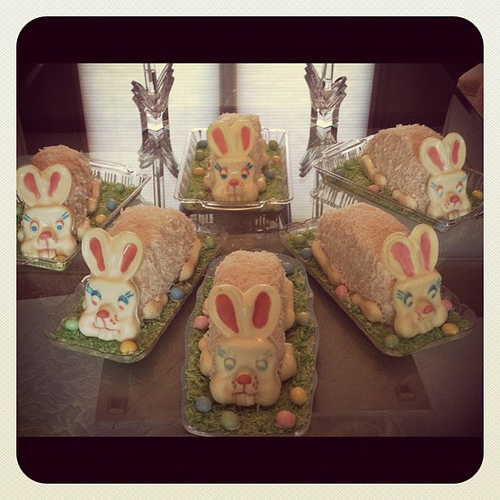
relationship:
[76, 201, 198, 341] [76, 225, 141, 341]
rabbit has platic face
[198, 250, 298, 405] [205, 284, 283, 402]
rabbit has platic face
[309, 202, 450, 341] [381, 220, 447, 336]
rabbit has platic face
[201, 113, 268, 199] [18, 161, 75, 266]
rabbit has platic face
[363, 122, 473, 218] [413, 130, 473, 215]
rabbit has platic face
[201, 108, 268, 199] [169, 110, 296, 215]
rabbit shaped om container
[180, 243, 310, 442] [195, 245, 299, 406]
eggs around cake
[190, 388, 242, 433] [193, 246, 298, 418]
eggs around cake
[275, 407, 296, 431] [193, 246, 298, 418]
eggs around cake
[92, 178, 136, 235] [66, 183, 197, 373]
eggs around cake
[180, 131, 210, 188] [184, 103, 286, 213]
eggs around cake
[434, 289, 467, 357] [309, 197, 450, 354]
eggs around cake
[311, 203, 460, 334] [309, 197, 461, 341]
cake like rabbit